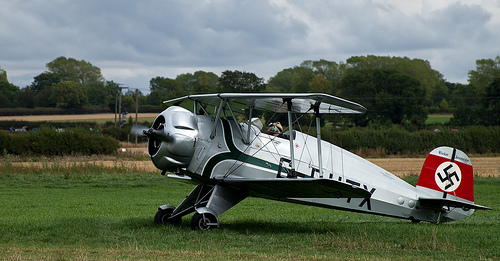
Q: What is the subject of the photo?
A: Plane.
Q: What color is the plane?
A: White.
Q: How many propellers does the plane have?
A: One.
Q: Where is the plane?
A: Ground.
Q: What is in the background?
A: Trees.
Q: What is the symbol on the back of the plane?
A: Swastika.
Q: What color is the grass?
A: Green.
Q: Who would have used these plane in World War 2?
A: Germans.